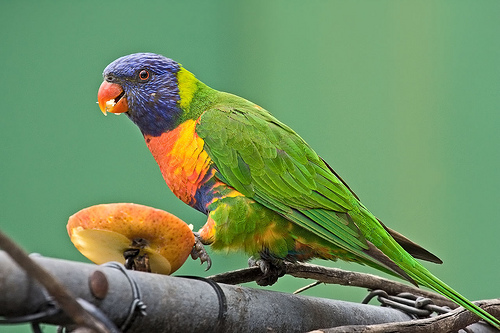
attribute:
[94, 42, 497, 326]
bird — parrot, tropical, blue, green, yellow, colorful, small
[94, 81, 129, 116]
beak — orange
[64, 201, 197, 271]
potato — slice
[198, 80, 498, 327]
wings — green, blue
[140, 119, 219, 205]
chest — red, yellow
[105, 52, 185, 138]
face — blue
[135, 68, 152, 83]
eye — bright orange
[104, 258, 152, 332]
wire — metal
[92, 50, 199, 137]
head — blue